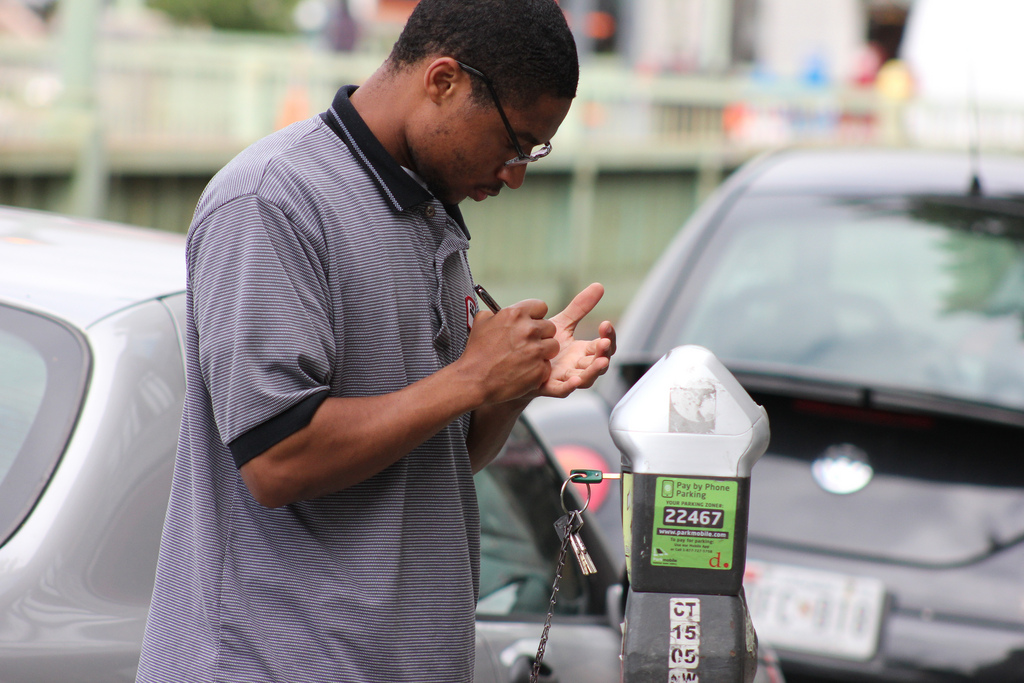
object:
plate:
[744, 558, 886, 661]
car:
[518, 144, 1024, 683]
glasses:
[458, 62, 553, 167]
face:
[435, 92, 572, 205]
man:
[132, 1, 617, 683]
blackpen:
[473, 284, 503, 316]